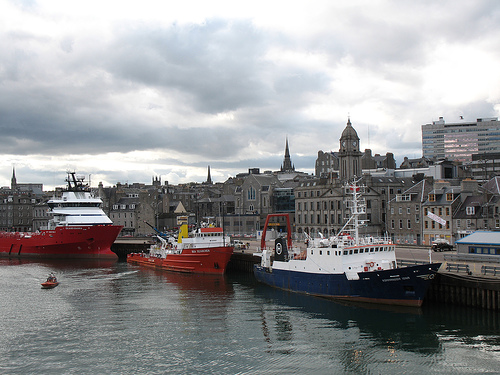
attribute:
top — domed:
[337, 115, 365, 147]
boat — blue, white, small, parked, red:
[9, 162, 442, 326]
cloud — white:
[5, 0, 499, 159]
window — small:
[6, 121, 498, 243]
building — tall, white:
[0, 115, 499, 277]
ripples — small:
[3, 259, 297, 375]